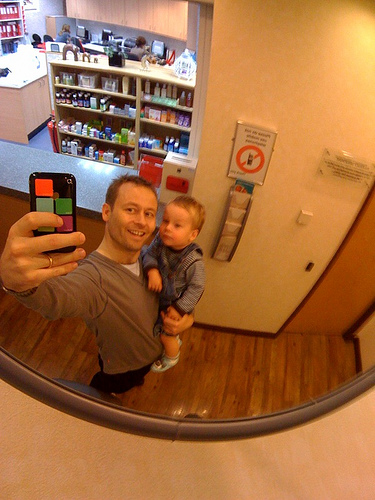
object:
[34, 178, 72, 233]
blocks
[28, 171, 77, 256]
phone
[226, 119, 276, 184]
sign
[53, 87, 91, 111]
bottles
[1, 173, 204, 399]
man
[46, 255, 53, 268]
ring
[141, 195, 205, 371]
boy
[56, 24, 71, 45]
person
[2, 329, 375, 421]
floor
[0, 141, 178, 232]
countertop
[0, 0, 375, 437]
reflection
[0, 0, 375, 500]
mirror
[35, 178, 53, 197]
square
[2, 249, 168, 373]
shirt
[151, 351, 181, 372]
shoe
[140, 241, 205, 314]
shirt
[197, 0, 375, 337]
wall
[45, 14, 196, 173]
shelf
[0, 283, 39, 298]
watch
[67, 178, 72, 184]
camera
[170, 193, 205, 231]
hair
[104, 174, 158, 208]
hair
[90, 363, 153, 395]
pants